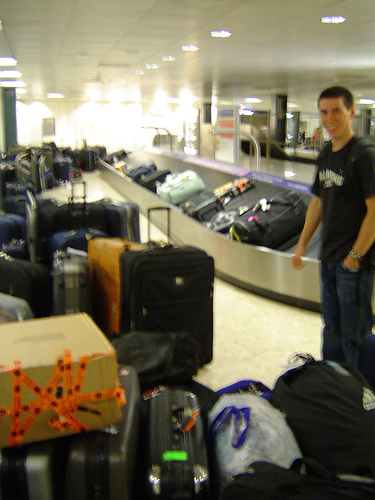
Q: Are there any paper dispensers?
A: No, there are no paper dispensers.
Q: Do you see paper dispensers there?
A: No, there are no paper dispensers.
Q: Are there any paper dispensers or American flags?
A: No, there are no paper dispensers or American flags.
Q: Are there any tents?
A: No, there are no tents.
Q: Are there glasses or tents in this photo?
A: No, there are no tents or glasses.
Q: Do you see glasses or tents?
A: No, there are no tents or glasses.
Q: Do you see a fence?
A: No, there are no fences.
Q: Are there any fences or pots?
A: No, there are no fences or pots.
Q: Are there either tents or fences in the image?
A: No, there are no tents or fences.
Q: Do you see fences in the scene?
A: No, there are no fences.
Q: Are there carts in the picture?
A: No, there are no carts.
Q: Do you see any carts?
A: No, there are no carts.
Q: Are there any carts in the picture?
A: No, there are no carts.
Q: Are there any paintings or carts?
A: No, there are no carts or paintings.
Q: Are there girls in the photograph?
A: No, there are no girls.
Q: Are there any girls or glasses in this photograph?
A: No, there are no girls or glasses.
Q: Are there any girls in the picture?
A: No, there are no girls.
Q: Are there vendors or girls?
A: No, there are no girls or vendors.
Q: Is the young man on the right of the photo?
A: Yes, the man is on the right of the image.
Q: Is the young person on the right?
A: Yes, the man is on the right of the image.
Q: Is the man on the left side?
A: No, the man is on the right of the image.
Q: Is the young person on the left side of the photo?
A: No, the man is on the right of the image.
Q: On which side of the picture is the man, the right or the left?
A: The man is on the right of the image.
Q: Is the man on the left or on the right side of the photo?
A: The man is on the right of the image.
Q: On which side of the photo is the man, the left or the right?
A: The man is on the right of the image.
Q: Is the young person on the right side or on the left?
A: The man is on the right of the image.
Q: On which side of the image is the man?
A: The man is on the right of the image.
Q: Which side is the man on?
A: The man is on the right of the image.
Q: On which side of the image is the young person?
A: The man is on the right of the image.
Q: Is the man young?
A: Yes, the man is young.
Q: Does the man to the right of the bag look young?
A: Yes, the man is young.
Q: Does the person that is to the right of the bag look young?
A: Yes, the man is young.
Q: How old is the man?
A: The man is young.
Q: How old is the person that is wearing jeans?
A: The man is young.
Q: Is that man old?
A: No, the man is young.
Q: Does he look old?
A: No, the man is young.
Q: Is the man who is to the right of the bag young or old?
A: The man is young.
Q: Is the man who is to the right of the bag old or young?
A: The man is young.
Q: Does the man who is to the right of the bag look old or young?
A: The man is young.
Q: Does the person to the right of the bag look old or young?
A: The man is young.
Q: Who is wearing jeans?
A: The man is wearing jeans.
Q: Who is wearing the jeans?
A: The man is wearing jeans.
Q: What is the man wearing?
A: The man is wearing jeans.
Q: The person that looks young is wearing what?
A: The man is wearing jeans.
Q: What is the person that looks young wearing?
A: The man is wearing jeans.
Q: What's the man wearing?
A: The man is wearing jeans.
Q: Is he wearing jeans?
A: Yes, the man is wearing jeans.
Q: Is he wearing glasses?
A: No, the man is wearing jeans.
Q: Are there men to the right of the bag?
A: Yes, there is a man to the right of the bag.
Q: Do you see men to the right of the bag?
A: Yes, there is a man to the right of the bag.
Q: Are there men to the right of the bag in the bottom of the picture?
A: Yes, there is a man to the right of the bag.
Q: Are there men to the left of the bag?
A: No, the man is to the right of the bag.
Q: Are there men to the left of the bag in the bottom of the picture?
A: No, the man is to the right of the bag.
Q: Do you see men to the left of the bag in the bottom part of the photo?
A: No, the man is to the right of the bag.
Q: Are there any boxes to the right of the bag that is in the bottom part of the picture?
A: No, there is a man to the right of the bag.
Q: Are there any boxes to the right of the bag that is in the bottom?
A: No, there is a man to the right of the bag.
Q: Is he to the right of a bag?
A: Yes, the man is to the right of a bag.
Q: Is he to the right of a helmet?
A: No, the man is to the right of a bag.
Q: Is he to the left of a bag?
A: No, the man is to the right of a bag.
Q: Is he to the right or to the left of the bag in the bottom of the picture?
A: The man is to the right of the bag.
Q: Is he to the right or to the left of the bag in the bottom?
A: The man is to the right of the bag.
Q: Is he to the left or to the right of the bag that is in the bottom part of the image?
A: The man is to the right of the bag.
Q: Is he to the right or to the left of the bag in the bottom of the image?
A: The man is to the right of the bag.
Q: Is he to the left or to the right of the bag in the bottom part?
A: The man is to the right of the bag.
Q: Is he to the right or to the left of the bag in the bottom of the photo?
A: The man is to the right of the bag.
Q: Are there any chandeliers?
A: No, there are no chandeliers.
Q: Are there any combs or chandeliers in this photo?
A: No, there are no chandeliers or combs.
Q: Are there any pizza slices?
A: No, there are no pizza slices.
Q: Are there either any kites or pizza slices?
A: No, there are no pizza slices or kites.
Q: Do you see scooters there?
A: No, there are no scooters.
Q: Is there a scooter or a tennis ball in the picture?
A: No, there are no scooters or tennis balls.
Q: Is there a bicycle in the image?
A: No, there are no bicycles.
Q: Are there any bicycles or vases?
A: No, there are no bicycles or vases.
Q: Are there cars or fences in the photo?
A: No, there are no cars or fences.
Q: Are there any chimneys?
A: No, there are no chimneys.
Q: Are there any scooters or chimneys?
A: No, there are no chimneys or scooters.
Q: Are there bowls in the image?
A: No, there are no bowls.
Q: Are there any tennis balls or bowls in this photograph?
A: No, there are no bowls or tennis balls.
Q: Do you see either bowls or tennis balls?
A: No, there are no bowls or tennis balls.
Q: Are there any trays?
A: No, there are no trays.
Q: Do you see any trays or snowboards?
A: No, there are no trays or snowboards.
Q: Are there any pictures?
A: No, there are no pictures.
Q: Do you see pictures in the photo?
A: No, there are no pictures.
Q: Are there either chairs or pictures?
A: No, there are no pictures or chairs.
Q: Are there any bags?
A: Yes, there is a bag.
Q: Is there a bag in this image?
A: Yes, there is a bag.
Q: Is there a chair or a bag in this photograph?
A: Yes, there is a bag.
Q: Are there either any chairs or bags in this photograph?
A: Yes, there is a bag.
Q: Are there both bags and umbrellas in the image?
A: No, there is a bag but no umbrellas.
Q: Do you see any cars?
A: No, there are no cars.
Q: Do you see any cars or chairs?
A: No, there are no cars or chairs.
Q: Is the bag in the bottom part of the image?
A: Yes, the bag is in the bottom of the image.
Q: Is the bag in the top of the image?
A: No, the bag is in the bottom of the image.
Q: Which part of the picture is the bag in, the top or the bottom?
A: The bag is in the bottom of the image.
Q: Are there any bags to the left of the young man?
A: Yes, there is a bag to the left of the man.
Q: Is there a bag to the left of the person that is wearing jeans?
A: Yes, there is a bag to the left of the man.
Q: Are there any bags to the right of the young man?
A: No, the bag is to the left of the man.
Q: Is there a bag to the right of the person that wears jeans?
A: No, the bag is to the left of the man.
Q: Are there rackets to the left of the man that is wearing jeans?
A: No, there is a bag to the left of the man.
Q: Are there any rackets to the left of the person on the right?
A: No, there is a bag to the left of the man.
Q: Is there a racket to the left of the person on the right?
A: No, there is a bag to the left of the man.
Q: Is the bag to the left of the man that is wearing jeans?
A: Yes, the bag is to the left of the man.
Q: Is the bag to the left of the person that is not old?
A: Yes, the bag is to the left of the man.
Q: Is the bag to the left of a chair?
A: No, the bag is to the left of the man.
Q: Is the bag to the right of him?
A: No, the bag is to the left of the man.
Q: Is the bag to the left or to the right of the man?
A: The bag is to the left of the man.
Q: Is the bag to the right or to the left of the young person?
A: The bag is to the left of the man.